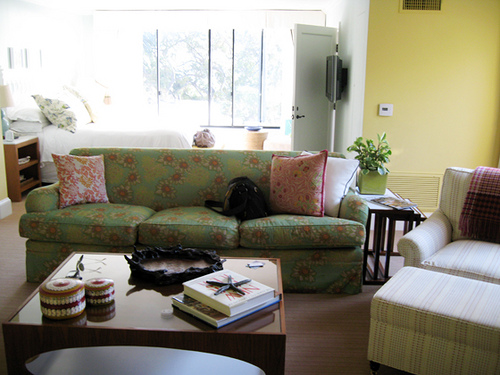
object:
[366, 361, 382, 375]
foot stool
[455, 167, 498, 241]
throw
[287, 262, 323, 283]
flower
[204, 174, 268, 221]
backpack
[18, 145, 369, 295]
couch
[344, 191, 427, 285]
end table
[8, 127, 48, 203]
nightstand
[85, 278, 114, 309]
container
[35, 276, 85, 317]
container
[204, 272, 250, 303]
starfish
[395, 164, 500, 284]
chair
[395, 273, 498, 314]
stripes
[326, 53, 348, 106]
television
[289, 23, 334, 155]
door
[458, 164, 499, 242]
blanket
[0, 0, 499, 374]
living room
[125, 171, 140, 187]
flowers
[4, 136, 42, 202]
end table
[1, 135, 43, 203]
table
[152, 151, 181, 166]
floral pattern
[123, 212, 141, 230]
pattern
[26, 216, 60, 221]
floral pattern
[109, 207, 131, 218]
floral pattern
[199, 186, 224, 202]
floral pattern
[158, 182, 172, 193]
floral pattern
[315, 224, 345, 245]
floral pattern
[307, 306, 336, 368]
floor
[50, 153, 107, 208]
pillow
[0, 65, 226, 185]
bed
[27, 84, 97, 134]
pillow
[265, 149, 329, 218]
pillow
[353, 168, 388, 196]
pot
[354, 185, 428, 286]
table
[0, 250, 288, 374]
table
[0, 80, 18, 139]
lamp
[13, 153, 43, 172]
shelf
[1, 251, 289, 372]
coffee table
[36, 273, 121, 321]
items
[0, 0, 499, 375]
scene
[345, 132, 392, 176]
house plant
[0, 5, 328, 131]
window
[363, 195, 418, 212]
magazine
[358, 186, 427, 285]
stand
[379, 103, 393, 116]
temperature gauge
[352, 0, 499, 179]
wall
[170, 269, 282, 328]
book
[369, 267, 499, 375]
ottoman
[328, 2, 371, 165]
wall